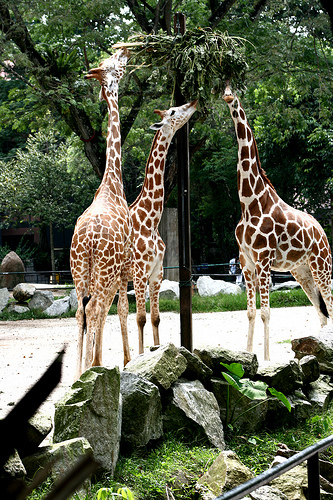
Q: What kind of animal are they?
A: Giraffe.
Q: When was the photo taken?
A: Daytime.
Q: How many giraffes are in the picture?
A: 3.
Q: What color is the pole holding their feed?
A: Black.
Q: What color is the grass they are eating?
A: Green.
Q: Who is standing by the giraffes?
A: Nobody.